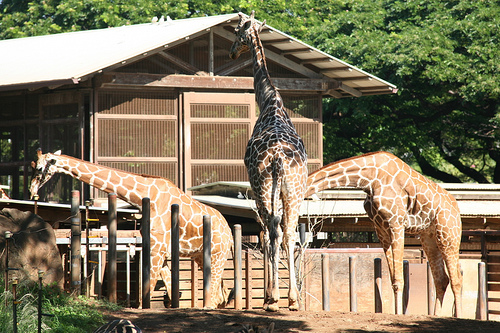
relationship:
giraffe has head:
[227, 3, 312, 315] [226, 6, 269, 62]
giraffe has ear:
[227, 3, 312, 315] [239, 18, 255, 34]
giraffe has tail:
[227, 3, 312, 315] [265, 164, 287, 268]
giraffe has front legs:
[21, 142, 238, 316] [142, 242, 180, 311]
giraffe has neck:
[227, 3, 312, 315] [247, 44, 290, 113]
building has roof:
[0, 12, 402, 195] [0, 8, 401, 102]